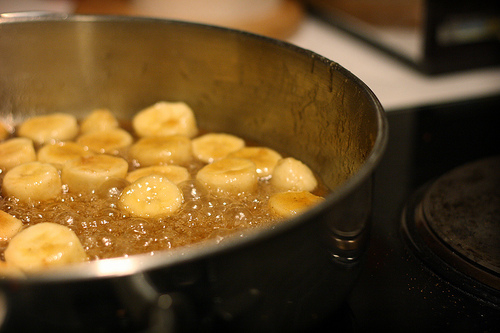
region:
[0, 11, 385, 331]
the pan on the stove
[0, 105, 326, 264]
the bubbling liquid in the pan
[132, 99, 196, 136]
the slice of food in the pan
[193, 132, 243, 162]
the slice of food in the pan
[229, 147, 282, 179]
the slice of food in the pan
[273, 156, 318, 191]
the slice of food in the pan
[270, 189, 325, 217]
the slice of food in the pan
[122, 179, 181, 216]
the slice of food in the pan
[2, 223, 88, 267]
the slice of food in the pan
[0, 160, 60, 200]
the slice of food in the pan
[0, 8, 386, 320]
saute pan on a burner on a kitchen stove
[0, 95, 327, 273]
slices of banana in a saute pan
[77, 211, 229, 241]
bubbles from boiling sauce in a saute pan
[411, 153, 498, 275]
burner on a black stove top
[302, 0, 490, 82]
chrome and black appliance in a kitchen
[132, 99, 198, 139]
single slice of banana cooking in a saute pan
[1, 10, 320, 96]
inside curved side of a saute pan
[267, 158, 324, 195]
end of a banana cooking in a saute pan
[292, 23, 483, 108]
part of a white counter in a kitchen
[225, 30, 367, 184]
sauce sticking to the side of a saute pan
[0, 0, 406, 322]
a pot in use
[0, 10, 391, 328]
the pot is black in color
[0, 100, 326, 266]
bananas are in the pot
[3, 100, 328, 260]
The bananas are tan in color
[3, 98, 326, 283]
the bananas are getting cooked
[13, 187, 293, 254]
bubbles are in the pot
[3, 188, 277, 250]
the bubbles are brown in color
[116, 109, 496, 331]
the stove is in use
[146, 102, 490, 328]
the stove in black in color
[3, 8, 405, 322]
the inside of the pot is silver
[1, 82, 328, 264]
Bananas sauteed in oil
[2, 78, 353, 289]
Caramelizing banana slices in a pan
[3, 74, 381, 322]
Boiling banana slices in a pan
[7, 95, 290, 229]
Carmalized bananas in a frying pan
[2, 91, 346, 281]
Seering scalops in a frying pan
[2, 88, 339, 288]
Scallops in boiling hot oil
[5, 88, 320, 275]
Scallops boiling in a pan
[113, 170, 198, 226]
A scallops in a hot oil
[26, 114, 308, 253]
Scallops frying in hot oil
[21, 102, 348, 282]
Frying scallops in a oil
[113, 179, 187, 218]
slice of banana cooking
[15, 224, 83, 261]
slice of banana cooking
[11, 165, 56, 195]
slice of banana cooking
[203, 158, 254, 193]
slice of banana cooking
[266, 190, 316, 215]
slice of banana cooking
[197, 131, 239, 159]
slice of banana cooking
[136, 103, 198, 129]
slice of banana cooking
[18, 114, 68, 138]
slice of banana cooking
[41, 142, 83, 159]
slice of banana cooking